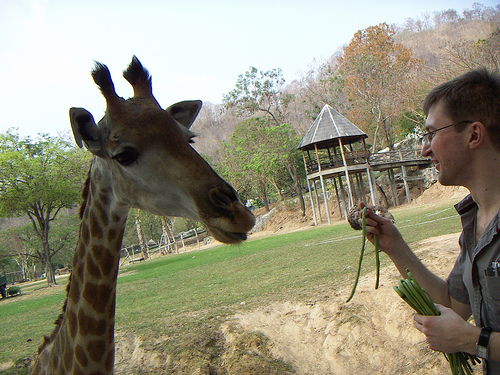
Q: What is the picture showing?
A: It is showing a zoo.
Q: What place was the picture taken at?
A: It was taken at the zoo.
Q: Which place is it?
A: It is a zoo.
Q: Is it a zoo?
A: Yes, it is a zoo.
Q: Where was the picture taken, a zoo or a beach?
A: It was taken at a zoo.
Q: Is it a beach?
A: No, it is a zoo.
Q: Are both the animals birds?
A: No, they are giraffes and birds.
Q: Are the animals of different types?
A: Yes, they are giraffes and birds.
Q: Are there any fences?
A: No, there are no fences.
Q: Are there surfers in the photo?
A: No, there are no surfers.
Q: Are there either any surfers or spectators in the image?
A: No, there are no surfers or spectators.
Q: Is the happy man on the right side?
A: Yes, the man is on the right of the image.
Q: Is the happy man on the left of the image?
A: No, the man is on the right of the image.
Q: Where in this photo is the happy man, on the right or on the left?
A: The man is on the right of the image.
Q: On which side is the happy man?
A: The man is on the right of the image.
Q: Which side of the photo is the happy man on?
A: The man is on the right of the image.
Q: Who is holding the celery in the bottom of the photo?
A: The man is holding the celery.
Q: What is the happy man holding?
A: The man is holding the celery.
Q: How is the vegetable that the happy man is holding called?
A: The vegetable is a celery.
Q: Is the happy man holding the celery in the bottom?
A: Yes, the man is holding the celery.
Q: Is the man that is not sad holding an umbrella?
A: No, the man is holding the celery.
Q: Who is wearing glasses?
A: The man is wearing glasses.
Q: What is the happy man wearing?
A: The man is wearing glasses.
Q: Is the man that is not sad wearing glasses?
A: Yes, the man is wearing glasses.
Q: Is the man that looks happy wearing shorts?
A: No, the man is wearing glasses.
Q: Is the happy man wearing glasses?
A: Yes, the man is wearing glasses.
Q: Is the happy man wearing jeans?
A: No, the man is wearing glasses.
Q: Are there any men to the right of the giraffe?
A: Yes, there is a man to the right of the giraffe.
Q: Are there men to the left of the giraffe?
A: No, the man is to the right of the giraffe.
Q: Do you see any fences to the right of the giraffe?
A: No, there is a man to the right of the giraffe.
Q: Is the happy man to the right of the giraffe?
A: Yes, the man is to the right of the giraffe.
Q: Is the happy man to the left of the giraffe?
A: No, the man is to the right of the giraffe.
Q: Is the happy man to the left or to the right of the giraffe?
A: The man is to the right of the giraffe.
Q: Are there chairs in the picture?
A: No, there are no chairs.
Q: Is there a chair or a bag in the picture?
A: No, there are no chairs or bags.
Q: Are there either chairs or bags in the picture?
A: No, there are no chairs or bags.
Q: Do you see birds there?
A: Yes, there is a bird.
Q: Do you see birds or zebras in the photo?
A: Yes, there is a bird.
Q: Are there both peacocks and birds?
A: No, there is a bird but no peacocks.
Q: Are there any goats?
A: No, there are no goats.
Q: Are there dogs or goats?
A: No, there are no goats or dogs.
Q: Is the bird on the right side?
A: Yes, the bird is on the right of the image.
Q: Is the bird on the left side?
A: No, the bird is on the right of the image.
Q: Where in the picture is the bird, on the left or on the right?
A: The bird is on the right of the image.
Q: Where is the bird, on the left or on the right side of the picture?
A: The bird is on the right of the image.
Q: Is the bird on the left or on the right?
A: The bird is on the right of the image.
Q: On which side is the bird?
A: The bird is on the right of the image.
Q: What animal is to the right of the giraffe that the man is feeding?
A: The animal is a bird.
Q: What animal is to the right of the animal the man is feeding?
A: The animal is a bird.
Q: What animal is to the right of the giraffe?
A: The animal is a bird.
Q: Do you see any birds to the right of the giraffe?
A: Yes, there is a bird to the right of the giraffe.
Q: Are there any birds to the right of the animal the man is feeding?
A: Yes, there is a bird to the right of the giraffe.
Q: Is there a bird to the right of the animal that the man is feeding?
A: Yes, there is a bird to the right of the giraffe.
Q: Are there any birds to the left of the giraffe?
A: No, the bird is to the right of the giraffe.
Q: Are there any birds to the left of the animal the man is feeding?
A: No, the bird is to the right of the giraffe.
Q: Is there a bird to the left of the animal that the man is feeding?
A: No, the bird is to the right of the giraffe.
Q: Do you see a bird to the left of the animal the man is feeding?
A: No, the bird is to the right of the giraffe.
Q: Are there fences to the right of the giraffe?
A: No, there is a bird to the right of the giraffe.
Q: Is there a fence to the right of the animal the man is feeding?
A: No, there is a bird to the right of the giraffe.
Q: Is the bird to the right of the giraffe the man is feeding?
A: Yes, the bird is to the right of the giraffe.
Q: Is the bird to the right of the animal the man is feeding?
A: Yes, the bird is to the right of the giraffe.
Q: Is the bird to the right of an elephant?
A: No, the bird is to the right of the giraffe.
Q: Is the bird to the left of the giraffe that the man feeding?
A: No, the bird is to the right of the giraffe.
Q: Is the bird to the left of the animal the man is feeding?
A: No, the bird is to the right of the giraffe.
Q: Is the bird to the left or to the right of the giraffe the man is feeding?
A: The bird is to the right of the giraffe.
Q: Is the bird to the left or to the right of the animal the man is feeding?
A: The bird is to the right of the giraffe.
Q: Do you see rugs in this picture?
A: No, there are no rugs.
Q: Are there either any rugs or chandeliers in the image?
A: No, there are no rugs or chandeliers.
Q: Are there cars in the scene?
A: No, there are no cars.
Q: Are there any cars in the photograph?
A: No, there are no cars.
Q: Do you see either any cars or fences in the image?
A: No, there are no cars or fences.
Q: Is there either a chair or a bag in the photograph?
A: No, there are no chairs or bags.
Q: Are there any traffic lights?
A: No, there are no traffic lights.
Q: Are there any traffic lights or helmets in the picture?
A: No, there are no traffic lights or helmets.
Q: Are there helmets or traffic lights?
A: No, there are no traffic lights or helmets.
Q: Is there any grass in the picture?
A: Yes, there is grass.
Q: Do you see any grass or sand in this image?
A: Yes, there is grass.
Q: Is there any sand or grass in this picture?
A: Yes, there is grass.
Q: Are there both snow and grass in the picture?
A: No, there is grass but no snow.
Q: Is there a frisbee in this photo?
A: No, there are no frisbees.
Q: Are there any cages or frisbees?
A: No, there are no frisbees or cages.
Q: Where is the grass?
A: The grass is on the ground.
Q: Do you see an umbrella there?
A: No, there are no umbrellas.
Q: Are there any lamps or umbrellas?
A: No, there are no umbrellas or lamps.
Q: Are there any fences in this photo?
A: No, there are no fences.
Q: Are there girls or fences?
A: No, there are no fences or girls.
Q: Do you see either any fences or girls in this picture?
A: No, there are no fences or girls.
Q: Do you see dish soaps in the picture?
A: No, there are no dish soaps.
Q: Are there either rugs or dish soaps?
A: No, there are no dish soaps or rugs.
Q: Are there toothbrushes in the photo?
A: No, there are no toothbrushes.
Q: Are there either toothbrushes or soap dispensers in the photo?
A: No, there are no toothbrushes or soap dispensers.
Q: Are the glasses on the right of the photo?
A: Yes, the glasses are on the right of the image.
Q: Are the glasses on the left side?
A: No, the glasses are on the right of the image.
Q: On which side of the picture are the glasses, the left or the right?
A: The glasses are on the right of the image.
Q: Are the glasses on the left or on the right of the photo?
A: The glasses are on the right of the image.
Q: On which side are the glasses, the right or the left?
A: The glasses are on the right of the image.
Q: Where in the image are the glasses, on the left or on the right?
A: The glasses are on the right of the image.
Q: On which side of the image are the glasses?
A: The glasses are on the right of the image.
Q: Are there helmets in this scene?
A: No, there are no helmets.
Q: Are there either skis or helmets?
A: No, there are no helmets or skis.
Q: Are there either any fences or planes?
A: No, there are no fences or planes.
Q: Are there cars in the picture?
A: No, there are no cars.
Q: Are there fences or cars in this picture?
A: No, there are no cars or fences.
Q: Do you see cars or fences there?
A: No, there are no cars or fences.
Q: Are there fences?
A: No, there are no fences.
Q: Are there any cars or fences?
A: No, there are no fences or cars.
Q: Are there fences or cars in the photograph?
A: No, there are no fences or cars.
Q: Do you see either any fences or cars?
A: No, there are no fences or cars.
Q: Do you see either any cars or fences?
A: No, there are no fences or cars.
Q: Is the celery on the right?
A: Yes, the celery is on the right of the image.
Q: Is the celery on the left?
A: No, the celery is on the right of the image.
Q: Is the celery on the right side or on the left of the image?
A: The celery is on the right of the image.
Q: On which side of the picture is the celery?
A: The celery is on the right of the image.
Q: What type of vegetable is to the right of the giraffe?
A: The vegetable is a celery.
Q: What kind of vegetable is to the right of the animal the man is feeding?
A: The vegetable is a celery.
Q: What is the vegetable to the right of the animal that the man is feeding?
A: The vegetable is a celery.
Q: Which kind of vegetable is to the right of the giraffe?
A: The vegetable is a celery.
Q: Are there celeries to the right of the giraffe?
A: Yes, there is a celery to the right of the giraffe.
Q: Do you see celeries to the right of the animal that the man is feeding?
A: Yes, there is a celery to the right of the giraffe.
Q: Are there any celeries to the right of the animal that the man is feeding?
A: Yes, there is a celery to the right of the giraffe.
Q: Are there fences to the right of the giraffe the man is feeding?
A: No, there is a celery to the right of the giraffe.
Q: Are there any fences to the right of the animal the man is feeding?
A: No, there is a celery to the right of the giraffe.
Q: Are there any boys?
A: No, there are no boys.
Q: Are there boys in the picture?
A: No, there are no boys.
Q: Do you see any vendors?
A: No, there are no vendors.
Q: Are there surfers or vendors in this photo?
A: No, there are no vendors or surfers.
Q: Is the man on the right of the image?
A: Yes, the man is on the right of the image.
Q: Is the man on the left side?
A: No, the man is on the right of the image.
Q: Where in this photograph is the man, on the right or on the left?
A: The man is on the right of the image.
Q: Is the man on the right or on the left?
A: The man is on the right of the image.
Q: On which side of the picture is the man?
A: The man is on the right of the image.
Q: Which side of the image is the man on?
A: The man is on the right of the image.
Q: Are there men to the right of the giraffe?
A: Yes, there is a man to the right of the giraffe.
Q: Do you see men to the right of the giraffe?
A: Yes, there is a man to the right of the giraffe.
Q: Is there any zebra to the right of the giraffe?
A: No, there is a man to the right of the giraffe.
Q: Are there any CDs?
A: No, there are no cds.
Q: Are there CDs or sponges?
A: No, there are no CDs or sponges.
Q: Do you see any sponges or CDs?
A: No, there are no CDs or sponges.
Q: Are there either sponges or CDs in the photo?
A: No, there are no CDs or sponges.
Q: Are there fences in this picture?
A: No, there are no fences.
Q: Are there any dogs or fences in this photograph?
A: No, there are no fences or dogs.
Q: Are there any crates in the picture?
A: No, there are no crates.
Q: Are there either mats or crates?
A: No, there are no crates or mats.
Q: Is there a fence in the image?
A: No, there are no fences.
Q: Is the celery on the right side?
A: Yes, the celery is on the right of the image.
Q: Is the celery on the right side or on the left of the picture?
A: The celery is on the right of the image.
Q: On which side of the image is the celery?
A: The celery is on the right of the image.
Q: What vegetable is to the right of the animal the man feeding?
A: The vegetable is a celery.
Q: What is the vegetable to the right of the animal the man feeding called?
A: The vegetable is a celery.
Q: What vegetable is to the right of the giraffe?
A: The vegetable is a celery.